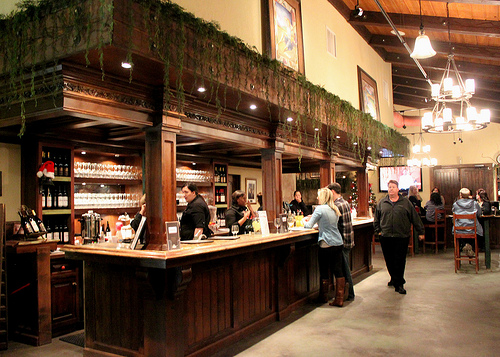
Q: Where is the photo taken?
A: In a bar.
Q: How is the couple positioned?
A: Bellied up to the bar.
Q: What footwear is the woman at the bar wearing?
A: Boots.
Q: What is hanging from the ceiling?
A: Light fixtures.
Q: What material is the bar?
A: Wood.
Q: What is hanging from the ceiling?
A: Light fixtures.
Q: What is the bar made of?
A: Wood.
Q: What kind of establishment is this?
A: A bar and grill.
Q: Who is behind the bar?
A: The bartenders.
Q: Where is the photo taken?
A: Bar.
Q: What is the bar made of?
A: Wood.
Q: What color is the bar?
A: Brown.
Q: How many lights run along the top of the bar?
A: Ten.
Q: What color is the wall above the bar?
A: Yellow.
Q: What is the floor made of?
A: Concrete.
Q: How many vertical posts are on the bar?
A: Four.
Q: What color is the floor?
A: Gray.